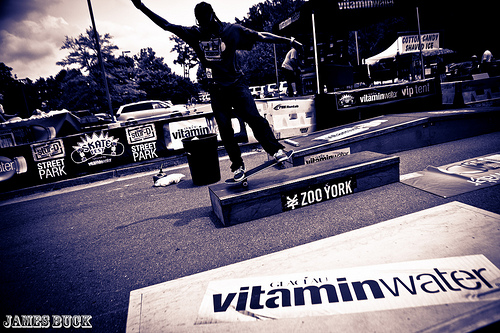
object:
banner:
[24, 137, 73, 186]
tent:
[272, 0, 400, 96]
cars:
[273, 80, 290, 95]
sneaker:
[271, 149, 289, 164]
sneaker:
[233, 164, 247, 182]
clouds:
[5, 17, 61, 65]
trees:
[58, 26, 149, 114]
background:
[0, 0, 272, 125]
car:
[113, 98, 183, 123]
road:
[1, 104, 500, 331]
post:
[83, 0, 117, 116]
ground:
[0, 62, 500, 333]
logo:
[208, 267, 496, 313]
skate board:
[224, 149, 297, 187]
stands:
[315, 75, 442, 129]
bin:
[181, 133, 221, 187]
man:
[130, 0, 307, 189]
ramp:
[265, 115, 426, 168]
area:
[0, 0, 496, 331]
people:
[280, 44, 309, 97]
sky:
[0, 0, 249, 79]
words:
[38, 169, 46, 179]